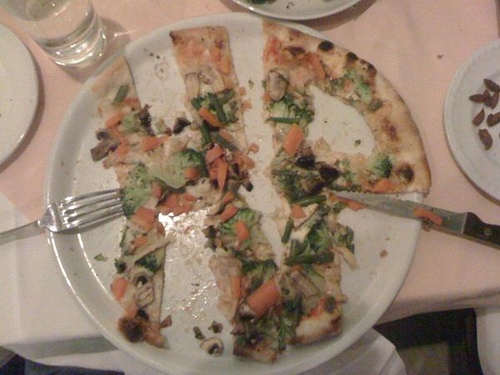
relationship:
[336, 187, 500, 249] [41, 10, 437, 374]
knife on plate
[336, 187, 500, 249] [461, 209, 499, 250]
knife has handle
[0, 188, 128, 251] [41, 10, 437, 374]
fork on plate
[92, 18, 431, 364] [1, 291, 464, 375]
dish hanging off edge of table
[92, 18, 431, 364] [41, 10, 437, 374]
dish on plate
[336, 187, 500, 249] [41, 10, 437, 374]
knife laying on plate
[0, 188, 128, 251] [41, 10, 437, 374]
fork laying on plate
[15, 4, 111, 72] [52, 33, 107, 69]
water reflecting light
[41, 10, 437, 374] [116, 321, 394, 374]
plate has edge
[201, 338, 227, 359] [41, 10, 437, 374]
crumb on plate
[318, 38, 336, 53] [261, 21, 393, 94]
spot on crust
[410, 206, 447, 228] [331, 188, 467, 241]
food on blade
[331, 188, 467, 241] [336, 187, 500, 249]
blade on knife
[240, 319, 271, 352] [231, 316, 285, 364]
meat in piece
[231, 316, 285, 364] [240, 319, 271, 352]
piece of meat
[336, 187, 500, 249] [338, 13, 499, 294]
knife on table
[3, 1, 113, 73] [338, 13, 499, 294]
glass on table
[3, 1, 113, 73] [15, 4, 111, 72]
glass of water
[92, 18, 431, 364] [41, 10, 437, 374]
pizza on plate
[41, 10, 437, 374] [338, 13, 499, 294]
plate on table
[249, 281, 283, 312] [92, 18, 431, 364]
carrot on dish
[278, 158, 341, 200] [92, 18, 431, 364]
broccoli on top of dish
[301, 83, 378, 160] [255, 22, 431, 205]
hole in slice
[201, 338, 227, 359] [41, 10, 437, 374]
mushroom on plate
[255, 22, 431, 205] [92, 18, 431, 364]
slice of pizza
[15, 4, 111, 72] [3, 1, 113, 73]
water inside glass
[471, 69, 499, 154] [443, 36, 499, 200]
nuts are on plate